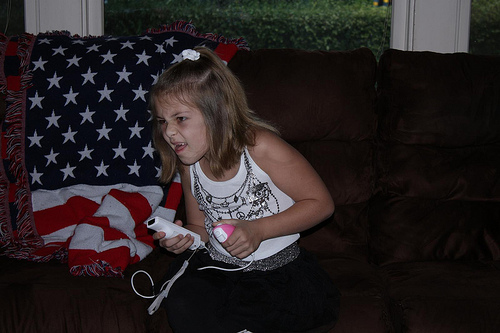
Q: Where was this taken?
A: Living room.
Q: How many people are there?
A: 1.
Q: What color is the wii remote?
A: White.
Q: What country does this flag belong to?
A: United States.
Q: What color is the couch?
A: Brown.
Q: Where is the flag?
A: On the blanket.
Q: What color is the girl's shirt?
A: White.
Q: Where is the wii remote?
A: In the girl's hand.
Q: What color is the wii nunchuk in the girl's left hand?
A: Pink.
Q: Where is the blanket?
A: Draped on the couch.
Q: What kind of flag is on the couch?
A: American.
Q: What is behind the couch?
A: A window.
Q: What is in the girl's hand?
A: Controller.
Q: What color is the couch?
A: Brown.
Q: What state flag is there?
A: USA.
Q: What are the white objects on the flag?
A: Stars.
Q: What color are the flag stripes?
A: Red and white.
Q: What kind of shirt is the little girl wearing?
A: Tank top.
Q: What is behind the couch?
A: Window.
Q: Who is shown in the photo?
A: A girl.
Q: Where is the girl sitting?
A: On a sofa.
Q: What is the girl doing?
A: Playing video games.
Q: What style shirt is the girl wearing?
A: Tank top.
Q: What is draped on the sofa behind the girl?
A: An American flag blanket.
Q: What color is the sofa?
A: Brown.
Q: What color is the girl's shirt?
A: White.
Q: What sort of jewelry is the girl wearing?
A: Necklace.